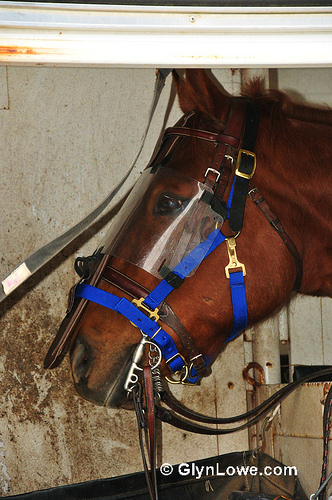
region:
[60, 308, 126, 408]
the nose of a horse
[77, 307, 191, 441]
the mouth of a horse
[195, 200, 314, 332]
the jaw of a horse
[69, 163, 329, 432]
the head of a horse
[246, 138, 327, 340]
the neck of a horse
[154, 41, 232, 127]
the ear of a horse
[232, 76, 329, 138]
the main of a horse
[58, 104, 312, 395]
the brown head of a horse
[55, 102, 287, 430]
the face of a horse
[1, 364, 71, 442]
a very dirty wall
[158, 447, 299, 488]
a photographer's watermark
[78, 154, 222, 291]
a visor guarding the horse's eyes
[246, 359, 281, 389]
a rusty hook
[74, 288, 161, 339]
a blue nylon strap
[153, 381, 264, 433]
a leather lead for a horse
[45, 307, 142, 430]
a brown horse's nose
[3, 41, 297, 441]
the head of a horse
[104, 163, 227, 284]
a plastic eye guard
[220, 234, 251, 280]
a gold colored clip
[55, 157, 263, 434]
the halter for a horse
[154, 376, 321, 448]
two leather straps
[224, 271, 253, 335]
a blue strap on a halter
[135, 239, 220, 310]
a blue strap on a halter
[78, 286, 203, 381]
a blue strap on a halter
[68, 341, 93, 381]
the nostril of a horse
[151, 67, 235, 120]
the ears of a horse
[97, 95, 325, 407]
the head of a horse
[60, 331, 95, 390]
the nose of a horse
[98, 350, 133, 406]
the mouth of a horse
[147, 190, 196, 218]
the eye of a horse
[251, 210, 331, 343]
the neck of a horse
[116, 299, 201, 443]
the reigns of a horse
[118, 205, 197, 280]
the eye guard of a horse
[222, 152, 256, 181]
the buckle of a reign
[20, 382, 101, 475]
a bunch of dirt on the wall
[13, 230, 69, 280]
the leash of a horse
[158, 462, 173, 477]
white copy write symbol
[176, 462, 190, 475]
the letter g in "GlynLowe.com"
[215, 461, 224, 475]
the letter L in "GlynLowe.com"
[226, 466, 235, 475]
the letter o in "GlynLowe.com"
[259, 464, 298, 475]
. com in in "GlynLowe.com"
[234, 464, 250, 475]
the letter w in "GlynLowe.com"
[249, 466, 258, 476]
the letter e in in "GlynLowe.com"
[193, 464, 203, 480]
the letter y in "GlynLowe.com"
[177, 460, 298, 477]
white text "GlynLowe.com"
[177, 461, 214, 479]
word Glyn in "GlynLowe.com"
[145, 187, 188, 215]
eye belongs to horse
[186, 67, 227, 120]
ear belongs to horse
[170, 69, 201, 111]
ear belongs to horse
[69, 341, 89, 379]
nostril belongs to horse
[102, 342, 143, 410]
mouth belongs to horse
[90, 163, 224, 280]
eye guard over eyes of horse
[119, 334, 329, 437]
reins attached to bit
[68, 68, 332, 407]
beautiful brown horse looking to the left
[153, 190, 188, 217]
the horse's left eye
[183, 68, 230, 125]
the horse's left ear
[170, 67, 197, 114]
the horse's right ear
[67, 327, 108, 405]
the nose of the horse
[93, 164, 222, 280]
a piece of clear plastic over the horse's eyes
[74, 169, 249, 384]
the blue harness on the horse's head